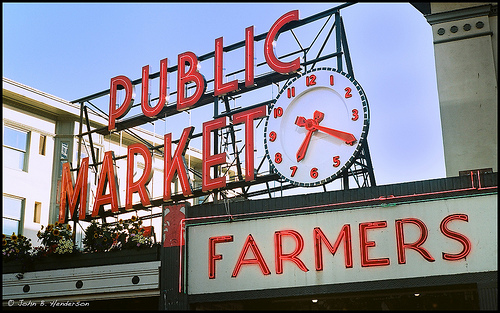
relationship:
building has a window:
[4, 77, 248, 253] [2, 122, 30, 172]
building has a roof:
[4, 77, 248, 253] [4, 77, 250, 178]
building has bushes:
[4, 77, 248, 253] [35, 224, 80, 254]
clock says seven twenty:
[265, 70, 368, 187] [294, 112, 360, 184]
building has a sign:
[4, 77, 248, 253] [180, 190, 499, 295]